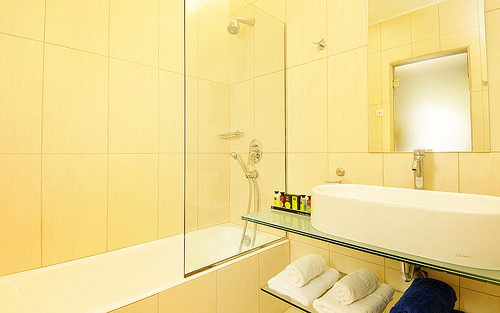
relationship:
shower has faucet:
[31, 9, 293, 263] [228, 134, 262, 190]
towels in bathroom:
[276, 258, 450, 312] [5, 11, 500, 311]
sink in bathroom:
[320, 170, 500, 263] [5, 11, 500, 311]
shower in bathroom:
[31, 9, 293, 263] [5, 11, 500, 311]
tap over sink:
[400, 141, 431, 185] [320, 170, 500, 263]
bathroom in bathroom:
[0, 0, 500, 311] [5, 11, 500, 311]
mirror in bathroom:
[369, 58, 479, 157] [5, 11, 500, 311]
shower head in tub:
[226, 14, 254, 38] [0, 220, 285, 311]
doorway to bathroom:
[390, 56, 469, 155] [5, 11, 500, 311]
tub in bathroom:
[0, 220, 285, 311] [5, 11, 500, 311]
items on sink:
[264, 185, 317, 215] [320, 170, 500, 263]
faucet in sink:
[395, 131, 425, 188] [320, 170, 500, 263]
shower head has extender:
[228, 134, 262, 190] [220, 182, 261, 264]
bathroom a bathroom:
[0, 0, 500, 311] [5, 11, 500, 311]